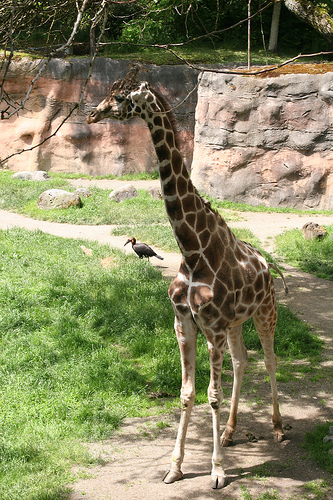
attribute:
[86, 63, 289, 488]
giraffe — facing left, large, lookig to the side, standing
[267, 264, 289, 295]
tail — small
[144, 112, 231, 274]
neck — long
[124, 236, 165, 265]
bird — black, small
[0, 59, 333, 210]
wall — rock wall, large, rocky, tall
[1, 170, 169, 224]
grass — green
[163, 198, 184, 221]
spot — brown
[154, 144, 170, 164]
spot — brown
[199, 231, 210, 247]
spot — brown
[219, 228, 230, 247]
spot — brown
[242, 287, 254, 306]
spot — brown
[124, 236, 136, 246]
head — red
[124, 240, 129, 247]
beak — long